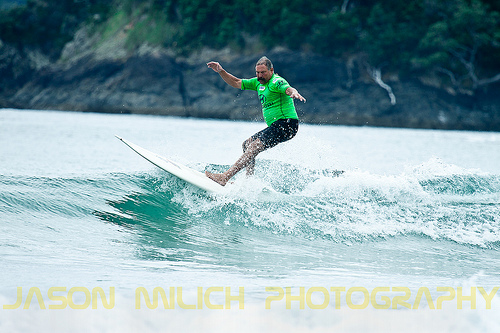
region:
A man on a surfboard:
[106, 50, 314, 207]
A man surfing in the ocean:
[102, 46, 327, 220]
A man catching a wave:
[106, 43, 321, 205]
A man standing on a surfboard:
[107, 48, 317, 207]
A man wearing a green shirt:
[202, 43, 327, 130]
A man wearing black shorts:
[246, 98, 315, 150]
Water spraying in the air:
[216, 127, 301, 184]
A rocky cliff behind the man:
[46, 34, 431, 123]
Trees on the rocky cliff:
[110, 13, 495, 66]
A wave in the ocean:
[300, 157, 479, 238]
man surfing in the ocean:
[124, 12, 330, 220]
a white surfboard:
[119, 133, 184, 175]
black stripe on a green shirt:
[279, 97, 287, 118]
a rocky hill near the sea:
[40, 51, 202, 111]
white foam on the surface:
[320, 208, 376, 235]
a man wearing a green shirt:
[206, 56, 313, 188]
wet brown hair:
[259, 55, 272, 65]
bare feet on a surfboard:
[203, 163, 230, 188]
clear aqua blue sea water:
[31, 159, 113, 235]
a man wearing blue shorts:
[224, 62, 314, 182]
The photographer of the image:
[0, 284, 497, 311]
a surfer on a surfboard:
[112, 53, 305, 193]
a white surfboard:
[115, 133, 238, 201]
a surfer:
[203, 58, 307, 184]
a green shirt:
[236, 72, 303, 124]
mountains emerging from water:
[3, 3, 499, 135]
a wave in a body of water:
[175, 156, 493, 243]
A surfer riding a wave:
[117, 56, 499, 249]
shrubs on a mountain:
[198, 0, 495, 87]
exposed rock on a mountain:
[32, 53, 499, 134]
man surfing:
[0, 24, 228, 162]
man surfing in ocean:
[108, 51, 340, 231]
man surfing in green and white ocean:
[115, 45, 301, 213]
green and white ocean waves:
[21, 169, 85, 215]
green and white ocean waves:
[93, 235, 212, 272]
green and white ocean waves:
[106, 185, 180, 243]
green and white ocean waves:
[210, 208, 283, 260]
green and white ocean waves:
[306, 181, 364, 256]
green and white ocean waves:
[369, 178, 418, 257]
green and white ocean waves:
[433, 153, 486, 236]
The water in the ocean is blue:
[18, 205, 458, 315]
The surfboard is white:
[107, 127, 259, 208]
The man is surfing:
[111, 55, 316, 202]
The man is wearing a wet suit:
[238, 76, 304, 150]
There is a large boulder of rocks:
[38, 60, 205, 111]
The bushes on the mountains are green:
[156, 5, 498, 62]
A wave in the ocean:
[7, 156, 484, 226]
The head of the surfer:
[249, 57, 278, 85]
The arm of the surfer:
[205, 56, 255, 103]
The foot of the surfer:
[201, 160, 229, 187]